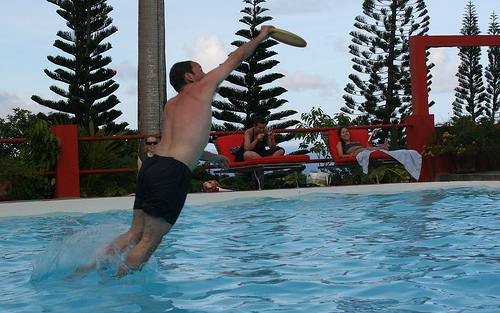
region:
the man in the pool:
[95, 40, 316, 279]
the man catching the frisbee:
[105, 13, 305, 284]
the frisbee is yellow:
[257, 21, 304, 58]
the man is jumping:
[53, 13, 323, 307]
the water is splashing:
[60, 223, 118, 268]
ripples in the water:
[276, 207, 450, 276]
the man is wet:
[56, 15, 320, 309]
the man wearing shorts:
[86, 17, 317, 301]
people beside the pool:
[146, 121, 390, 165]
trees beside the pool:
[62, 10, 494, 105]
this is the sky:
[176, 7, 226, 40]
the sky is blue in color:
[183, 0, 222, 32]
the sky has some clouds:
[285, 66, 338, 106]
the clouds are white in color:
[291, 55, 339, 111]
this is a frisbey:
[262, 18, 307, 53]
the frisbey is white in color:
[277, 32, 292, 42]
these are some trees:
[47, 0, 497, 115]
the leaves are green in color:
[254, 61, 271, 98]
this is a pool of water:
[236, 197, 498, 296]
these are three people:
[104, 56, 372, 258]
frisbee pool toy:
[260, 22, 309, 52]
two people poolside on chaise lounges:
[217, 113, 426, 181]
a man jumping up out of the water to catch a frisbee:
[99, 23, 310, 275]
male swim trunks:
[128, 151, 195, 225]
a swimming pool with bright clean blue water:
[8, 180, 498, 312]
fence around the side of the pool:
[2, 113, 436, 197]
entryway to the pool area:
[407, 32, 497, 175]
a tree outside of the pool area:
[27, 1, 133, 133]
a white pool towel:
[353, 147, 426, 180]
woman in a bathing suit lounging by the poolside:
[328, 125, 423, 182]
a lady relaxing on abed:
[329, 121, 415, 168]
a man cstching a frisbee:
[90, 20, 306, 282]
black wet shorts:
[130, 147, 189, 225]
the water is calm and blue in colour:
[248, 213, 453, 294]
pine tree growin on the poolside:
[34, 0, 121, 114]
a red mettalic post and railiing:
[41, 118, 86, 207]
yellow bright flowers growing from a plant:
[423, 138, 480, 151]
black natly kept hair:
[166, 63, 188, 88]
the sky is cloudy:
[306, 5, 348, 87]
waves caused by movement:
[19, 233, 79, 270]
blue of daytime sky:
[0, 0, 497, 113]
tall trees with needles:
[30, 0, 497, 140]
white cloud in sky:
[186, 35, 226, 70]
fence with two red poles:
[1, 113, 433, 195]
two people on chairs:
[215, 117, 397, 172]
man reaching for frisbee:
[117, 24, 306, 259]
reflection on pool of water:
[1, 187, 498, 312]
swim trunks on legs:
[120, 155, 194, 251]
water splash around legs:
[32, 223, 152, 288]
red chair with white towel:
[329, 127, 422, 179]